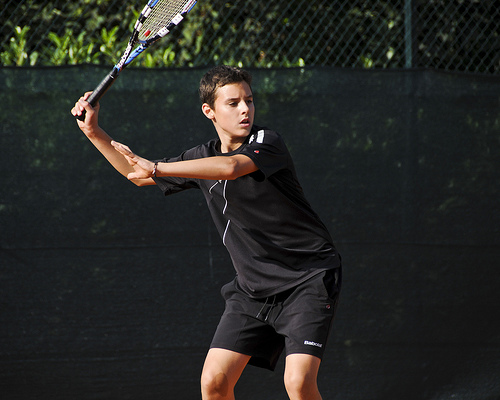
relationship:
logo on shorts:
[300, 337, 325, 350] [179, 277, 354, 368]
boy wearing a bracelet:
[170, 52, 310, 194] [150, 157, 171, 188]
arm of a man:
[109, 139, 260, 186] [64, 63, 351, 397]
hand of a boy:
[111, 140, 155, 181] [70, 63, 345, 399]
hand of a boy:
[65, 87, 110, 129] [70, 63, 345, 399]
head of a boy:
[189, 60, 262, 142] [70, 63, 345, 399]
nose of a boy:
[220, 93, 257, 120] [70, 63, 345, 399]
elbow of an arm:
[224, 156, 241, 178] [108, 130, 271, 187]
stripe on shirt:
[257, 121, 267, 148] [154, 131, 336, 281]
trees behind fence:
[54, 15, 266, 63] [21, 10, 463, 71]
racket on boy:
[75, 0, 192, 123] [70, 62, 342, 399]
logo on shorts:
[300, 337, 325, 350] [208, 263, 344, 363]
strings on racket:
[137, 1, 191, 31] [75, 0, 192, 123]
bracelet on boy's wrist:
[153, 160, 159, 179] [151, 156, 161, 176]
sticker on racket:
[146, 27, 154, 41] [67, 0, 204, 125]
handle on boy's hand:
[75, 69, 110, 117] [70, 91, 95, 131]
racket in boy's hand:
[71, 0, 193, 119] [70, 91, 95, 131]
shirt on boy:
[145, 124, 348, 301] [70, 62, 342, 399]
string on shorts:
[253, 296, 278, 326] [212, 267, 340, 369]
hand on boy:
[107, 137, 160, 197] [171, 62, 376, 336]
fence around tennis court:
[4, 6, 466, 396] [1, 1, 465, 393]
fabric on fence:
[7, 62, 484, 387] [376, 112, 471, 228]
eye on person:
[227, 91, 256, 107] [74, 56, 346, 396]